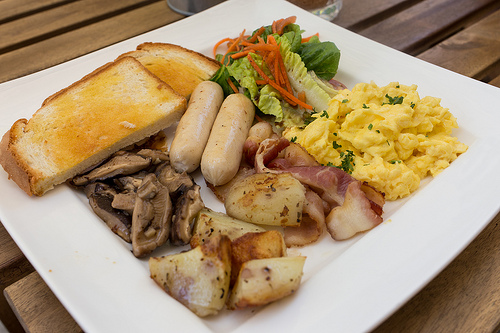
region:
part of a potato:
[242, 257, 285, 300]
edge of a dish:
[32, 262, 67, 309]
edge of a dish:
[158, 230, 205, 271]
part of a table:
[447, 271, 485, 315]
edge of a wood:
[0, 277, 27, 309]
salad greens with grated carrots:
[219, 29, 334, 95]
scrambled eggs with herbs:
[335, 93, 450, 175]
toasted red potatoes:
[192, 199, 304, 304]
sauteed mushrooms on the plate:
[91, 178, 200, 228]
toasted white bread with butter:
[5, 43, 157, 196]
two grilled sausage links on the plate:
[187, 82, 250, 177]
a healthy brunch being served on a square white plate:
[23, 33, 460, 304]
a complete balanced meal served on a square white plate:
[7, 37, 484, 299]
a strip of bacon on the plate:
[272, 152, 372, 203]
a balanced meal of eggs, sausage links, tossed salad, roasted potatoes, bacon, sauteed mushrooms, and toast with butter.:
[23, 15, 433, 314]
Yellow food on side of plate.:
[350, 131, 426, 176]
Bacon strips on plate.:
[295, 147, 350, 221]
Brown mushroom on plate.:
[124, 184, 187, 245]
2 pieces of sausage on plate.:
[183, 91, 242, 180]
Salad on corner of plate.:
[233, 39, 305, 118]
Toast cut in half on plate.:
[90, 57, 180, 156]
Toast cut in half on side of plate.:
[91, 47, 163, 158]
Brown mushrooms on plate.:
[110, 166, 163, 213]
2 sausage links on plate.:
[178, 108, 233, 178]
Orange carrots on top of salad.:
[236, 16, 295, 113]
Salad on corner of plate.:
[236, 13, 322, 143]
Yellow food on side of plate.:
[331, 92, 428, 179]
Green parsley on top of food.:
[329, 100, 376, 231]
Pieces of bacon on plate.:
[296, 147, 391, 269]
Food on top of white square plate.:
[71, 52, 404, 289]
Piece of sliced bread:
[0, 40, 225, 192]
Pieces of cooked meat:
[70, 138, 208, 249]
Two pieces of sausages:
[167, 77, 259, 189]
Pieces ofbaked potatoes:
[147, 211, 308, 322]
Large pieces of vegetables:
[211, 10, 341, 122]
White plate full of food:
[0, 0, 498, 330]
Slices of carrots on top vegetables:
[210, 11, 315, 111]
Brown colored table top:
[392, 1, 499, 50]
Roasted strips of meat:
[255, 128, 394, 215]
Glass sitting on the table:
[149, 0, 349, 22]